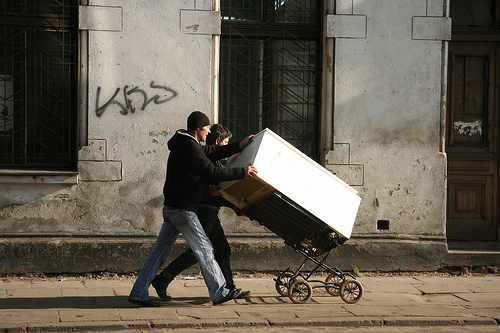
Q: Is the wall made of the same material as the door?
A: No, the wall is made of cement and the door is made of wood.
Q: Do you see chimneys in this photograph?
A: No, there are no chimneys.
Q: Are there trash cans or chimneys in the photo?
A: No, there are no chimneys or trash cans.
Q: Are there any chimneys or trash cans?
A: No, there are no chimneys or trash cans.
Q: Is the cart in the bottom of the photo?
A: Yes, the cart is in the bottom of the image.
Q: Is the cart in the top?
A: No, the cart is in the bottom of the image.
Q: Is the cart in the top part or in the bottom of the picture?
A: The cart is in the bottom of the image.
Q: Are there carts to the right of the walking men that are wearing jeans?
A: Yes, there is a cart to the right of the men.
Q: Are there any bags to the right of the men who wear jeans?
A: No, there is a cart to the right of the men.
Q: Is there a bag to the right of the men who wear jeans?
A: No, there is a cart to the right of the men.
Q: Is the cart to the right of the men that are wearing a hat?
A: Yes, the cart is to the right of the men.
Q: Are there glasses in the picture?
A: No, there are no glasses.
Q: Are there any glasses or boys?
A: No, there are no glasses or boys.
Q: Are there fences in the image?
A: No, there are no fences.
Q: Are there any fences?
A: No, there are no fences.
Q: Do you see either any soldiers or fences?
A: No, there are no fences or soldiers.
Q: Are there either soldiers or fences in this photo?
A: No, there are no fences or soldiers.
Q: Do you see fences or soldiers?
A: No, there are no fences or soldiers.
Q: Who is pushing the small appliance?
A: The men are pushing the appliance.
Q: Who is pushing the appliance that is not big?
A: The men are pushing the appliance.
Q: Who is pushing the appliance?
A: The men are pushing the appliance.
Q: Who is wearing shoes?
A: The men are wearing shoes.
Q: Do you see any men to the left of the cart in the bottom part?
A: Yes, there are men to the left of the cart.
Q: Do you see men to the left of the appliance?
A: Yes, there are men to the left of the appliance.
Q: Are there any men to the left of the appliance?
A: Yes, there are men to the left of the appliance.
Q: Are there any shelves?
A: No, there are no shelves.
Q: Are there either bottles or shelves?
A: No, there are no shelves or bottles.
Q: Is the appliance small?
A: Yes, the appliance is small.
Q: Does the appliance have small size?
A: Yes, the appliance is small.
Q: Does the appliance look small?
A: Yes, the appliance is small.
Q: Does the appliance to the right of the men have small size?
A: Yes, the appliance is small.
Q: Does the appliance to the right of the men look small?
A: Yes, the appliance is small.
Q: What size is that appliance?
A: The appliance is small.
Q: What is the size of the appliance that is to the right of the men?
A: The appliance is small.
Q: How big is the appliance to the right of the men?
A: The appliance is small.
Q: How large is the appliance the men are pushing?
A: The appliance is small.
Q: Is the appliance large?
A: No, the appliance is small.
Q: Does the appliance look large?
A: No, the appliance is small.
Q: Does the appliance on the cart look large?
A: No, the appliance is small.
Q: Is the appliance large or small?
A: The appliance is small.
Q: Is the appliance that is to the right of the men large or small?
A: The appliance is small.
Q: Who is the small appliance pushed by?
A: The appliance is pushed by the men.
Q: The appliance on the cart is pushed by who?
A: The appliance is pushed by the men.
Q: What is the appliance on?
A: The appliance is on the cart.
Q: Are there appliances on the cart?
A: Yes, there is an appliance on the cart.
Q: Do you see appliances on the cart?
A: Yes, there is an appliance on the cart.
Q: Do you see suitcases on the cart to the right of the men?
A: No, there is an appliance on the cart.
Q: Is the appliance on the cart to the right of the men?
A: Yes, the appliance is on the cart.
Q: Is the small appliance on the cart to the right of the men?
A: Yes, the appliance is on the cart.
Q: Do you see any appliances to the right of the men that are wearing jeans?
A: Yes, there is an appliance to the right of the men.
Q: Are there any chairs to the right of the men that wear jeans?
A: No, there is an appliance to the right of the men.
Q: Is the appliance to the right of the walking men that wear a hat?
A: Yes, the appliance is to the right of the men.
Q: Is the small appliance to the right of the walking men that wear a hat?
A: Yes, the appliance is to the right of the men.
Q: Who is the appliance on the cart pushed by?
A: The appliance is pushed by the men.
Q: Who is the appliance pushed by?
A: The appliance is pushed by the men.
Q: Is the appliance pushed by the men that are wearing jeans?
A: Yes, the appliance is pushed by the men.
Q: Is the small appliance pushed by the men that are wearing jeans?
A: Yes, the appliance is pushed by the men.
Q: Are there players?
A: No, there are no players.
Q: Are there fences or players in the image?
A: No, there are no players or fences.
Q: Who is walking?
A: The men are walking.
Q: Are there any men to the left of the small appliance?
A: Yes, there are men to the left of the appliance.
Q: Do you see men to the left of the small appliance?
A: Yes, there are men to the left of the appliance.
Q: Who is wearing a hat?
A: The men are wearing a hat.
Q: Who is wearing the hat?
A: The men are wearing a hat.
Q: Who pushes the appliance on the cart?
A: The men push the appliance.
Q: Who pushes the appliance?
A: The men push the appliance.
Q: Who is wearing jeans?
A: The men are wearing jeans.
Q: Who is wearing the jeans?
A: The men are wearing jeans.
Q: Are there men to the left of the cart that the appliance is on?
A: Yes, there are men to the left of the cart.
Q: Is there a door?
A: Yes, there is a door.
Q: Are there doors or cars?
A: Yes, there is a door.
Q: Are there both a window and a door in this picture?
A: Yes, there are both a door and a window.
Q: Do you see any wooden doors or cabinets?
A: Yes, there is a wood door.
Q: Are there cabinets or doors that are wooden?
A: Yes, the door is wooden.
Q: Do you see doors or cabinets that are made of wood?
A: Yes, the door is made of wood.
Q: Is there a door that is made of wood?
A: Yes, there is a door that is made of wood.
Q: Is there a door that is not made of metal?
A: Yes, there is a door that is made of wood.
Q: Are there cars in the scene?
A: No, there are no cars.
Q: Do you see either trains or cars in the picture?
A: No, there are no cars or trains.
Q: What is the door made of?
A: The door is made of wood.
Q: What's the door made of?
A: The door is made of wood.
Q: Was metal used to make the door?
A: No, the door is made of wood.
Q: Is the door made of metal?
A: No, the door is made of wood.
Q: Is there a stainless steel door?
A: No, there is a door but it is made of wood.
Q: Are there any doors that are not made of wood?
A: No, there is a door but it is made of wood.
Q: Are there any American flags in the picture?
A: No, there are no American flags.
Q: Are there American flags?
A: No, there are no American flags.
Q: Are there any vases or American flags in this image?
A: No, there are no American flags or vases.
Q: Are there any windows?
A: Yes, there is a window.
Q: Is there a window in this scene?
A: Yes, there is a window.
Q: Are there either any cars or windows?
A: Yes, there is a window.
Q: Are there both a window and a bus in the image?
A: No, there is a window but no buses.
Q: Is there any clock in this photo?
A: No, there are no clocks.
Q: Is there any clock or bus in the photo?
A: No, there are no clocks or buses.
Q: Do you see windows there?
A: Yes, there is a window.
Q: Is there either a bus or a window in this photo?
A: Yes, there is a window.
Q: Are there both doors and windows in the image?
A: Yes, there are both a window and a door.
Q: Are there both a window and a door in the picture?
A: Yes, there are both a window and a door.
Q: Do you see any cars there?
A: No, there are no cars.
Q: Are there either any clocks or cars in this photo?
A: No, there are no cars or clocks.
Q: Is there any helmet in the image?
A: No, there are no helmets.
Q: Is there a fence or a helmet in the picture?
A: No, there are no helmets or fences.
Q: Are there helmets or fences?
A: No, there are no helmets or fences.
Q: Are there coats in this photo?
A: Yes, there is a coat.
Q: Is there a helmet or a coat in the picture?
A: Yes, there is a coat.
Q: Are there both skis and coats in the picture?
A: No, there is a coat but no skis.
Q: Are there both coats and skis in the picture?
A: No, there is a coat but no skis.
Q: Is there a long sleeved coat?
A: Yes, there is a long sleeved coat.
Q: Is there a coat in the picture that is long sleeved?
A: Yes, there is a coat that is long sleeved.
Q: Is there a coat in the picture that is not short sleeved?
A: Yes, there is a long sleeved coat.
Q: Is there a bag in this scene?
A: No, there are no bags.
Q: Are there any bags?
A: No, there are no bags.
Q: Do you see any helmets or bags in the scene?
A: No, there are no bags or helmets.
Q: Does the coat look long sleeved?
A: Yes, the coat is long sleeved.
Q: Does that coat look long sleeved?
A: Yes, the coat is long sleeved.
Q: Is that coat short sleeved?
A: No, the coat is long sleeved.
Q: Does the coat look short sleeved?
A: No, the coat is long sleeved.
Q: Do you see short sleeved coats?
A: No, there is a coat but it is long sleeved.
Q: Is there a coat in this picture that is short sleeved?
A: No, there is a coat but it is long sleeved.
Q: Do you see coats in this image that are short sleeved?
A: No, there is a coat but it is long sleeved.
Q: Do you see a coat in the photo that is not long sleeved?
A: No, there is a coat but it is long sleeved.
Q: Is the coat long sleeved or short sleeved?
A: The coat is long sleeved.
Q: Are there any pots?
A: No, there are no pots.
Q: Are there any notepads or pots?
A: No, there are no pots or notepads.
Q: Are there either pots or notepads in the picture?
A: No, there are no pots or notepads.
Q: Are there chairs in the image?
A: No, there are no chairs.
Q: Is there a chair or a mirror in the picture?
A: No, there are no chairs or mirrors.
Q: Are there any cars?
A: No, there are no cars.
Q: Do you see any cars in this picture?
A: No, there are no cars.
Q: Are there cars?
A: No, there are no cars.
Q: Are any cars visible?
A: No, there are no cars.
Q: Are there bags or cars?
A: No, there are no cars or bags.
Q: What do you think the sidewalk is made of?
A: The sidewalk is made of brick.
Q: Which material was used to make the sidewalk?
A: The sidewalk is made of brick.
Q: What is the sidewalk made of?
A: The sidewalk is made of brick.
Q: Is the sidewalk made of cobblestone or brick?
A: The sidewalk is made of brick.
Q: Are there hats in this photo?
A: Yes, there is a hat.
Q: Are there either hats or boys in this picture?
A: Yes, there is a hat.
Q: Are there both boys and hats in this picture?
A: No, there is a hat but no boys.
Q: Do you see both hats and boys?
A: No, there is a hat but no boys.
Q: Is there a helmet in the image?
A: No, there are no helmets.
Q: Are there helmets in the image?
A: No, there are no helmets.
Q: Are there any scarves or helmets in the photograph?
A: No, there are no helmets or scarves.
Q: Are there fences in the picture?
A: No, there are no fences.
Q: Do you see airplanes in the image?
A: No, there are no airplanes.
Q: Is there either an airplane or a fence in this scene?
A: No, there are no airplanes or fences.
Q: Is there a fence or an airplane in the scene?
A: No, there are no airplanes or fences.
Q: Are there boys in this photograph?
A: No, there are no boys.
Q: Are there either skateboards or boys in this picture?
A: No, there are no boys or skateboards.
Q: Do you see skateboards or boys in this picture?
A: No, there are no boys or skateboards.